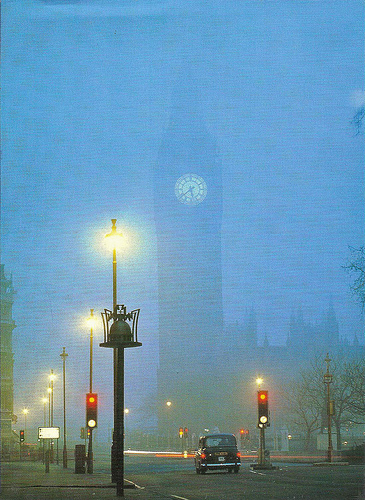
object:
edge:
[129, 476, 140, 485]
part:
[333, 377, 346, 392]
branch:
[331, 369, 340, 390]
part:
[116, 237, 123, 245]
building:
[154, 53, 224, 441]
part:
[203, 255, 213, 276]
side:
[247, 462, 364, 488]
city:
[0, 49, 365, 500]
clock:
[173, 170, 208, 208]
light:
[99, 229, 132, 257]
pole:
[112, 238, 117, 430]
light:
[87, 395, 97, 406]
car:
[194, 432, 242, 473]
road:
[0, 453, 365, 500]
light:
[200, 453, 207, 460]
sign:
[38, 426, 61, 439]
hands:
[190, 185, 195, 198]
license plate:
[218, 456, 226, 462]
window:
[206, 436, 236, 447]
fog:
[41, 33, 136, 108]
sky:
[0, 0, 365, 344]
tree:
[296, 352, 365, 450]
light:
[258, 391, 268, 402]